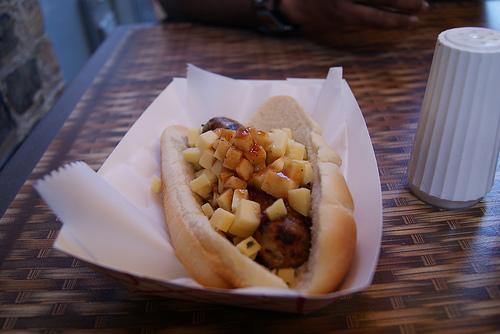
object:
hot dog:
[203, 114, 311, 270]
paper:
[33, 62, 353, 294]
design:
[76, 257, 345, 315]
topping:
[185, 128, 313, 256]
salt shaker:
[403, 27, 498, 210]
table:
[1, 26, 499, 334]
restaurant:
[0, 1, 498, 334]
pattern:
[2, 28, 499, 334]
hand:
[272, 0, 427, 58]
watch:
[250, 0, 299, 37]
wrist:
[235, 0, 306, 36]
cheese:
[235, 235, 260, 259]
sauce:
[217, 130, 275, 184]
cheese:
[287, 186, 313, 219]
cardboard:
[51, 75, 383, 314]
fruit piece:
[198, 132, 219, 149]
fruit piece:
[230, 198, 263, 238]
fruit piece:
[260, 171, 297, 200]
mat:
[1, 28, 499, 333]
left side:
[157, 123, 290, 290]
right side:
[248, 94, 356, 297]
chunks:
[271, 138, 287, 156]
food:
[159, 94, 358, 295]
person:
[150, 0, 433, 53]